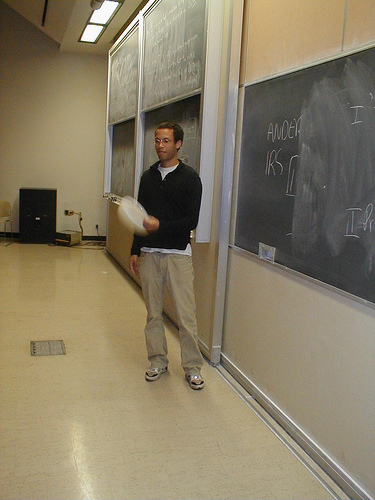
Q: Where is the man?
A: Classroom.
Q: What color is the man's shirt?
A: Black.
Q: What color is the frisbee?
A: White.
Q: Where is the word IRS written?
A: On the blackboard.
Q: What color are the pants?
A: Tan.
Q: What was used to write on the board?
A: Chalk.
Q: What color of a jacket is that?
A: Black.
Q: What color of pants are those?
A: Tan.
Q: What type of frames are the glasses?
A: Wire frame.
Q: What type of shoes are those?
A: Tennis shoes.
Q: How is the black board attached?
A: It is affixed to the wall with screws.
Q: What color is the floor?
A: Tan.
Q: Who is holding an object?
A: A man.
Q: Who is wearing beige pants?
A: A man.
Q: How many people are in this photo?
A: 1.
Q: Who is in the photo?
A: The man.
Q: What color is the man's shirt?
A: Black.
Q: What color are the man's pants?
A: Khaki.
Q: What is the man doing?
A: Holding a plate.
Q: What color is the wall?
A: Tan.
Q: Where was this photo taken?
A: A classroom.